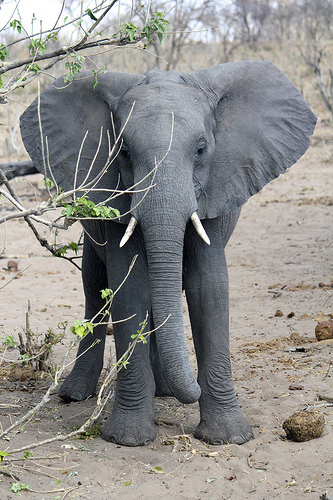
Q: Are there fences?
A: No, there are no fences.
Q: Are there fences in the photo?
A: No, there are no fences.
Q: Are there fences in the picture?
A: No, there are no fences.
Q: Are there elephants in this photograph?
A: Yes, there is an elephant.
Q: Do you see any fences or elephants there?
A: Yes, there is an elephant.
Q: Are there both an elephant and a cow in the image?
A: No, there is an elephant but no cows.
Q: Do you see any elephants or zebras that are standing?
A: Yes, the elephant is standing.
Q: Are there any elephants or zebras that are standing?
A: Yes, the elephant is standing.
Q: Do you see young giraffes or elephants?
A: Yes, there is a young elephant.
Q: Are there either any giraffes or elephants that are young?
A: Yes, the elephant is young.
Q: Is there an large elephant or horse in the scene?
A: Yes, there is a large elephant.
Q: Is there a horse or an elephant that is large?
A: Yes, the elephant is large.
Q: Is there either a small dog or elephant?
A: Yes, there is a small elephant.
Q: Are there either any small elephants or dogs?
A: Yes, there is a small elephant.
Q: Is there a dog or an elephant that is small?
A: Yes, the elephant is small.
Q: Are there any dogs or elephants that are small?
A: Yes, the elephant is small.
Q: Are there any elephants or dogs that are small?
A: Yes, the elephant is small.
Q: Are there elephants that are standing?
A: Yes, there is an elephant that is standing.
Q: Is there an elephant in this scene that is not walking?
A: Yes, there is an elephant that is standing.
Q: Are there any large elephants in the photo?
A: Yes, there is a large elephant.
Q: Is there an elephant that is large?
A: Yes, there is an elephant that is large.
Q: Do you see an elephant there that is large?
A: Yes, there is an elephant that is large.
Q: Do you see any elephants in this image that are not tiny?
A: Yes, there is a large elephant.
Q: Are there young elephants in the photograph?
A: Yes, there is a young elephant.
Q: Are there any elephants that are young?
A: Yes, there is an elephant that is young.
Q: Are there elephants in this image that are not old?
A: Yes, there is an young elephant.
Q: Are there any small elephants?
A: Yes, there is a small elephant.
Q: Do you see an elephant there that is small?
A: Yes, there is an elephant that is small.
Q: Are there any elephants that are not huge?
A: Yes, there is a small elephant.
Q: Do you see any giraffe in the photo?
A: No, there are no giraffes.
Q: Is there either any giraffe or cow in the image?
A: No, there are no giraffes or cows.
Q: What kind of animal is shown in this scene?
A: The animal is an elephant.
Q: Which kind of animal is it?
A: The animal is an elephant.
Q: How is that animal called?
A: That is an elephant.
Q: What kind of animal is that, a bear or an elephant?
A: That is an elephant.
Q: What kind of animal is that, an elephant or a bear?
A: That is an elephant.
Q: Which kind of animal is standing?
A: The animal is an elephant.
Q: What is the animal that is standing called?
A: The animal is an elephant.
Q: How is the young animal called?
A: The animal is an elephant.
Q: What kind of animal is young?
A: The animal is an elephant.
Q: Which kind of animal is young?
A: The animal is an elephant.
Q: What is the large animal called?
A: The animal is an elephant.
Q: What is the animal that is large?
A: The animal is an elephant.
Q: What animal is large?
A: The animal is an elephant.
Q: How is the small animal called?
A: The animal is an elephant.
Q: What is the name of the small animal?
A: The animal is an elephant.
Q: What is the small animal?
A: The animal is an elephant.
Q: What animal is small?
A: The animal is an elephant.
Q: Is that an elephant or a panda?
A: That is an elephant.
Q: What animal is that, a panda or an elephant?
A: That is an elephant.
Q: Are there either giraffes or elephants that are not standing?
A: No, there is an elephant but it is standing.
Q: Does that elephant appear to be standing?
A: Yes, the elephant is standing.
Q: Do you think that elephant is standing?
A: Yes, the elephant is standing.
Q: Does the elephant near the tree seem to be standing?
A: Yes, the elephant is standing.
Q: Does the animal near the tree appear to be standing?
A: Yes, the elephant is standing.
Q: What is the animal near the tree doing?
A: The elephant is standing.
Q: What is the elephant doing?
A: The elephant is standing.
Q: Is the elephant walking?
A: No, the elephant is standing.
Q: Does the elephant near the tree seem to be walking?
A: No, the elephant is standing.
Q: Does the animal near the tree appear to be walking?
A: No, the elephant is standing.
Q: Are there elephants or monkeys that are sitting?
A: No, there is an elephant but it is standing.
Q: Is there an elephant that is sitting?
A: No, there is an elephant but it is standing.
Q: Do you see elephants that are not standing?
A: No, there is an elephant but it is standing.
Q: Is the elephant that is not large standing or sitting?
A: The elephant is standing.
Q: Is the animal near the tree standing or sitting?
A: The elephant is standing.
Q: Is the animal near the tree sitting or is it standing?
A: The elephant is standing.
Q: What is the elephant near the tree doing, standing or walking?
A: The elephant is standing.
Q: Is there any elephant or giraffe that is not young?
A: No, there is an elephant but it is young.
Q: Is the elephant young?
A: Yes, the elephant is young.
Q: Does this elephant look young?
A: Yes, the elephant is young.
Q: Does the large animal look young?
A: Yes, the elephant is young.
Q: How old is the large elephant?
A: The elephant is young.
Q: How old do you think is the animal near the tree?
A: The elephant is young.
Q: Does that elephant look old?
A: No, the elephant is young.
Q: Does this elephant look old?
A: No, the elephant is young.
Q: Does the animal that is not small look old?
A: No, the elephant is young.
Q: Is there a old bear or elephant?
A: No, there is an elephant but it is young.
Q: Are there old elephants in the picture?
A: No, there is an elephant but it is young.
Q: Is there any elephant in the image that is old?
A: No, there is an elephant but it is young.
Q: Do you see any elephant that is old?
A: No, there is an elephant but it is young.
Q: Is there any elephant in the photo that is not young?
A: No, there is an elephant but it is young.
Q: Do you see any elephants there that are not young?
A: No, there is an elephant but it is young.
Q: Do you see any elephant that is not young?
A: No, there is an elephant but it is young.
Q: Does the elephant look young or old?
A: The elephant is young.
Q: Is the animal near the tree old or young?
A: The elephant is young.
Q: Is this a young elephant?
A: Yes, this is a young elephant.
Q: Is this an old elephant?
A: No, this is a young elephant.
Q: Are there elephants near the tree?
A: Yes, there is an elephant near the tree.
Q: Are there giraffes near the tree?
A: No, there is an elephant near the tree.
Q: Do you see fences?
A: No, there are no fences.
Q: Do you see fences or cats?
A: No, there are no fences or cats.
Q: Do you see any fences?
A: No, there are no fences.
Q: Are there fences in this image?
A: No, there are no fences.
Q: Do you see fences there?
A: No, there are no fences.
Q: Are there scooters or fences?
A: No, there are no fences or scooters.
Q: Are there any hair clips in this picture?
A: No, there are no hair clips.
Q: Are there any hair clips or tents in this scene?
A: No, there are no hair clips or tents.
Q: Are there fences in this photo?
A: No, there are no fences.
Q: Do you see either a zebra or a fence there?
A: No, there are no fences or zebras.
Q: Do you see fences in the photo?
A: No, there are no fences.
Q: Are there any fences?
A: No, there are no fences.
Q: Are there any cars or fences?
A: No, there are no fences or cars.